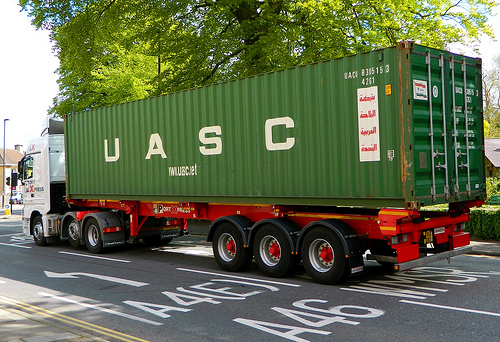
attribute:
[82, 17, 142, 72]
trees — green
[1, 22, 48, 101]
sky — white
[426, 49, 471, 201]
bars — metal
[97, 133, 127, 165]
letter — white 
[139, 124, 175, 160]
letter — white 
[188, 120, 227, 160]
letter — white 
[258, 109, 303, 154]
letter — white 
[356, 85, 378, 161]
sign — white 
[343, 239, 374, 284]
mudflap — black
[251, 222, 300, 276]
tire — black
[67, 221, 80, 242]
rim — industrial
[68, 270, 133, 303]
road — dark grey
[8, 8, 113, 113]
sky — bright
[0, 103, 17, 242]
lamp — tall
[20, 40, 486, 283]
truck — black, green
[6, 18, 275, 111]
sky — white, grey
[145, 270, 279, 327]
pavement — gray 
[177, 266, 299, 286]
line — white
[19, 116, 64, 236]
cab — white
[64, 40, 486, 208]
container — green, large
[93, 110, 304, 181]
name — white 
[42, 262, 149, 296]
arrow — white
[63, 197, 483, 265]
bed — red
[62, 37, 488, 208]
trucks — white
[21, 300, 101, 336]
lines — yellow